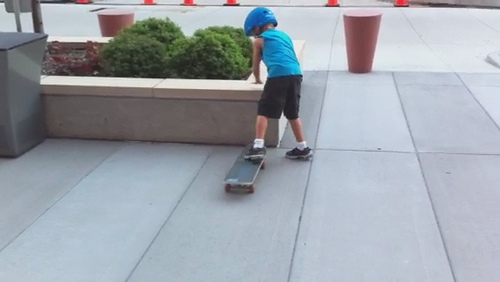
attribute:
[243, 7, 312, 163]
child — skateboarding, young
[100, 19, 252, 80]
bushes — green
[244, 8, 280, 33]
helmet — blue, protective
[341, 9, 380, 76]
pot — red, tall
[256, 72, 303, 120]
shorts — black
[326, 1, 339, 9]
safety cone — orange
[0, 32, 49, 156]
garbage can — gray, metal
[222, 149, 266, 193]
skateboard — black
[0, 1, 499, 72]
sidewalk — gray, concrete, tiled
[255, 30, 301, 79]
tank top — blue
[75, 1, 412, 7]
traffic cones — orange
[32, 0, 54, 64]
trunk of tree — gray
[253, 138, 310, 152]
socks — white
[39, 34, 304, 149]
planter — concrete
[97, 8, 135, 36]
pot — red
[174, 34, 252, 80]
bush — round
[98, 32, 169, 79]
bush — green